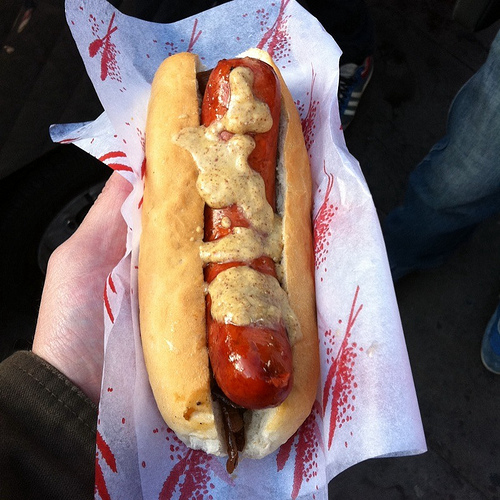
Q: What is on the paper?
A: A red design.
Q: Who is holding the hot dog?
A: A man is holding a hot dog.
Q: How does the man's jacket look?
A: It is brown in color.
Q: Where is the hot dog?
A: The hot dog is over paper.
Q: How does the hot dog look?
A: The hot dog is red in color.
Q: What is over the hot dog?
A: Mustard is over the hot dog.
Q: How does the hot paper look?
A: The paper is white and red.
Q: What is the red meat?
A: A hotdog.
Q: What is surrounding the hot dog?
A: A bun.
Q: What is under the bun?
A: A paper wrapper.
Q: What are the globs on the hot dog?
A: Mustard.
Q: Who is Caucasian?
A: Ther person, holding the hot dog.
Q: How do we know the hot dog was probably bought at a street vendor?
A: Because the pavement is visible.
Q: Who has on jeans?
A: A person, standing on the sidewalk, in front of the person with the hot dog.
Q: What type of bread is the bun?
A: White.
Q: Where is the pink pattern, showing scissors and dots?
A: On the wrapper, below the hot dog.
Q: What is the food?
A: A hotdog.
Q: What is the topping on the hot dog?
A: Mustard.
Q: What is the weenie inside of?
A: A bun.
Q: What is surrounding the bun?
A: Paper.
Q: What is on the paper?
A: A hot dog.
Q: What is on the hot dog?
A: Brown mustand.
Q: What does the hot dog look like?
A: Dark red.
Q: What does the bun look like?
A: Light brown.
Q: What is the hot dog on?
A: Parchment paper.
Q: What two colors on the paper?
A: Red and white.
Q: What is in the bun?
A: Hot dog.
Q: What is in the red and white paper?
A: The bun.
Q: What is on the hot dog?
A: Mustard.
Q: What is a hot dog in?
A: A bun.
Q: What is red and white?
A: Paper.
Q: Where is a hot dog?
A: In a hand.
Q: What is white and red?
A: Wrapper.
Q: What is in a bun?
A: Hot dog.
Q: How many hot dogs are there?
A: One.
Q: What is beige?
A: Sauce on hot dog.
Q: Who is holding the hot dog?
A: A person.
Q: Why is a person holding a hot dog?
A: To eat it.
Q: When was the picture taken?
A: Daytime.